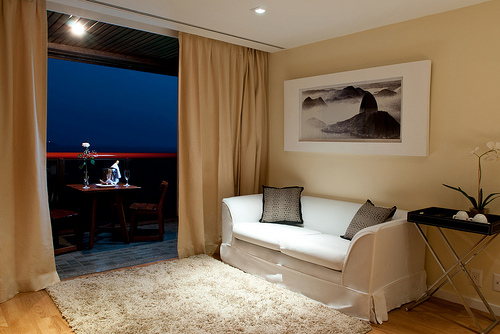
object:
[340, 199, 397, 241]
pillow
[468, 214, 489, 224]
cups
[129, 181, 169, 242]
chair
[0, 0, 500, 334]
room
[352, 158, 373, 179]
bad negative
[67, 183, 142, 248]
table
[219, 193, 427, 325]
couch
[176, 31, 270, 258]
curtains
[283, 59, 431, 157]
frame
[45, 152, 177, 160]
bar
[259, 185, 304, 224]
pillows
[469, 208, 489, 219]
planter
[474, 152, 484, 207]
stem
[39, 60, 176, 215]
outside view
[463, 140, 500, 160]
flower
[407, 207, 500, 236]
serving tray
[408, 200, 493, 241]
tray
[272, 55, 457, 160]
hanging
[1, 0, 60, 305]
curtain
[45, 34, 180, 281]
terrace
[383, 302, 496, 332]
flooring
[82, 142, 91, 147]
rose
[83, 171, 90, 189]
vase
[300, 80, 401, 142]
image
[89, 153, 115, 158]
sign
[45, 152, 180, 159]
pole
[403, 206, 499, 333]
stand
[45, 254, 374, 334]
carpet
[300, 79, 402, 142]
art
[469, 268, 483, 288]
outlets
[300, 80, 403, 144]
sign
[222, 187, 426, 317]
couch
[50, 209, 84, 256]
chairs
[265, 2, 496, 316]
wall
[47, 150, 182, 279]
balcony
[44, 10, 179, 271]
door